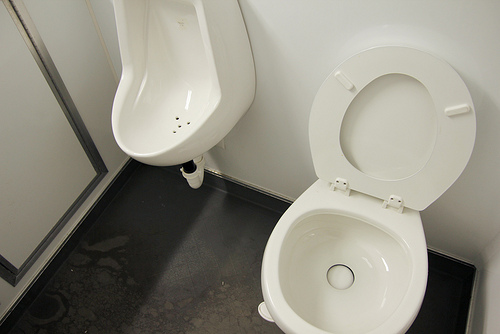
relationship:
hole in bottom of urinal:
[174, 115, 180, 121] [108, 0, 257, 168]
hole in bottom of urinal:
[185, 118, 192, 126] [108, 0, 257, 168]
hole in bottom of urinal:
[177, 123, 181, 129] [108, 0, 257, 168]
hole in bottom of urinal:
[170, 129, 177, 136] [108, 0, 257, 168]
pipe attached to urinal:
[180, 153, 205, 190] [108, 0, 257, 168]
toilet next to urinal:
[261, 44, 478, 333] [108, 0, 257, 168]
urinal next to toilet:
[108, 0, 257, 168] [261, 44, 478, 333]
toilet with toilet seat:
[261, 44, 478, 333] [306, 44, 477, 213]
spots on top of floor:
[13, 234, 266, 333] [7, 163, 465, 334]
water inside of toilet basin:
[294, 228, 381, 319] [260, 181, 429, 333]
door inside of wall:
[0, 1, 102, 277] [0, 2, 132, 325]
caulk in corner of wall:
[87, 0, 121, 87] [0, 2, 132, 325]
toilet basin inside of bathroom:
[260, 181, 429, 333] [1, 1, 499, 333]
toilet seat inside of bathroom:
[306, 44, 477, 213] [1, 1, 499, 333]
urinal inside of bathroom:
[108, 0, 257, 168] [1, 1, 499, 333]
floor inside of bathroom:
[7, 163, 465, 334] [1, 1, 499, 333]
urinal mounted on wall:
[108, 0, 257, 168] [88, 1, 498, 268]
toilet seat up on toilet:
[306, 44, 477, 213] [261, 44, 478, 333]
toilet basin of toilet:
[260, 181, 429, 333] [261, 44, 478, 333]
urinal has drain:
[108, 0, 257, 168] [171, 111, 190, 137]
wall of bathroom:
[0, 2, 132, 325] [1, 1, 499, 333]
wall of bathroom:
[88, 1, 498, 268] [1, 1, 499, 333]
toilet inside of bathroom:
[261, 44, 478, 333] [1, 1, 499, 333]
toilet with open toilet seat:
[261, 44, 478, 333] [306, 44, 477, 213]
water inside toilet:
[294, 228, 381, 319] [261, 44, 478, 333]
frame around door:
[1, 1, 109, 288] [0, 1, 102, 277]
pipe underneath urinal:
[180, 153, 205, 190] [108, 0, 257, 168]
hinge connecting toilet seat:
[329, 176, 352, 200] [306, 44, 477, 213]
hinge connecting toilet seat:
[384, 194, 407, 217] [306, 44, 477, 213]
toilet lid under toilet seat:
[339, 70, 436, 182] [306, 44, 477, 213]